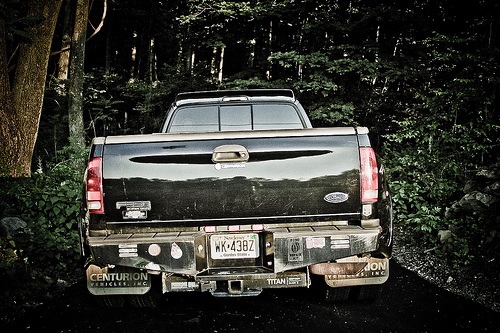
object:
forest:
[7, 0, 497, 323]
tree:
[382, 62, 497, 272]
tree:
[289, 0, 327, 123]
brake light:
[359, 147, 378, 203]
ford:
[74, 74, 408, 315]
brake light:
[80, 156, 120, 206]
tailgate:
[83, 129, 379, 221]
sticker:
[87, 262, 157, 297]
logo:
[323, 190, 349, 205]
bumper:
[85, 226, 382, 261]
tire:
[96, 267, 183, 309]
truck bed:
[82, 125, 394, 295]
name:
[117, 200, 149, 210]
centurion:
[87, 270, 148, 287]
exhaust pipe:
[305, 250, 375, 284]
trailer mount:
[227, 274, 247, 296]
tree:
[67, 0, 92, 156]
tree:
[2, 0, 67, 174]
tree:
[54, 6, 74, 98]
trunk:
[0, 0, 58, 180]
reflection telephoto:
[161, 176, 263, 209]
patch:
[301, 311, 329, 322]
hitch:
[228, 277, 243, 294]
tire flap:
[82, 264, 154, 295]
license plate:
[211, 235, 260, 260]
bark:
[21, 77, 37, 119]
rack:
[177, 90, 308, 106]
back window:
[169, 102, 302, 128]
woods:
[4, 0, 496, 300]